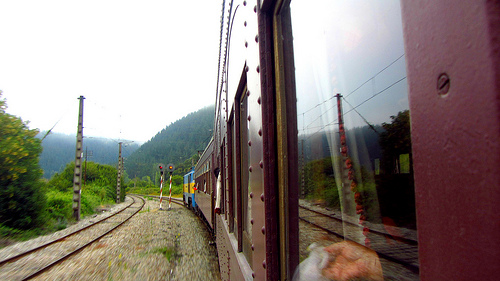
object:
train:
[178, 0, 499, 280]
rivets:
[252, 34, 260, 42]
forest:
[123, 103, 213, 176]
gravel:
[87, 246, 149, 268]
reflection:
[317, 57, 392, 121]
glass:
[276, 1, 416, 278]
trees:
[170, 134, 187, 146]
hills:
[106, 156, 182, 191]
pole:
[168, 173, 172, 213]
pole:
[158, 167, 163, 211]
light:
[169, 165, 173, 169]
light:
[156, 163, 163, 170]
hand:
[322, 241, 381, 279]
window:
[229, 64, 247, 253]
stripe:
[180, 182, 198, 194]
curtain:
[303, 0, 386, 253]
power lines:
[117, 142, 130, 155]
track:
[2, 193, 147, 279]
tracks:
[154, 196, 185, 206]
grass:
[3, 212, 54, 233]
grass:
[157, 243, 181, 266]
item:
[297, 242, 330, 281]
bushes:
[3, 120, 43, 225]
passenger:
[316, 230, 425, 280]